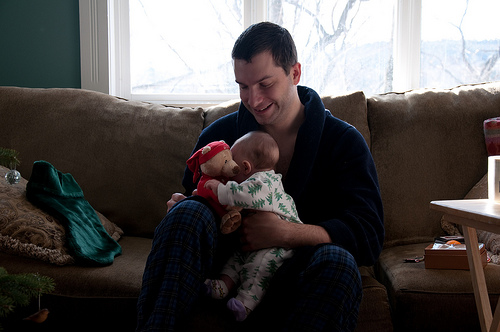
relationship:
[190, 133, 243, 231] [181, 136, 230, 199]
bear wearing pajamas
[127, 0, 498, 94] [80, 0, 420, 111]
window has frame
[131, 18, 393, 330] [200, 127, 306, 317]
man holding baby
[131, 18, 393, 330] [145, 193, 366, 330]
man wearing pants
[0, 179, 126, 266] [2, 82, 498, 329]
pillow on couch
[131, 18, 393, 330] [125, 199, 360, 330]
man wearing pants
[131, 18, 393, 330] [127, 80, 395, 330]
man wearing robe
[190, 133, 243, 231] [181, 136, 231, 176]
bear wearing hat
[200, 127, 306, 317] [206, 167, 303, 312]
baby wearing pjs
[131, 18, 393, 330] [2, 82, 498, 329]
man sitting on couch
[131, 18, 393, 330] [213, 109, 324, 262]
man with baby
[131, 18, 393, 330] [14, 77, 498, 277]
man on couch